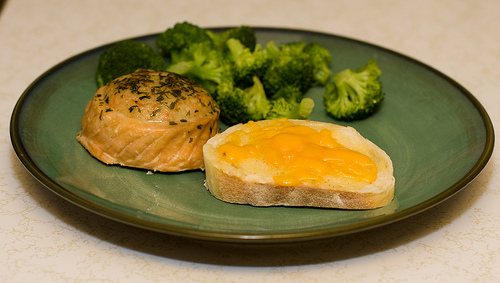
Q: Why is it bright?
A: Lights are on.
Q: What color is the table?
A: Tan.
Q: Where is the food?
A: The plate.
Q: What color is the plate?
A: Green.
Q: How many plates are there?
A: One.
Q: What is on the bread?
A: Cheese.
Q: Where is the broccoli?
A: The back.